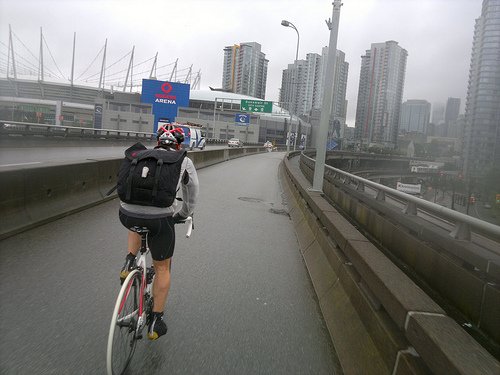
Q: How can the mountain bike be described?
A: A white and red mountain bike.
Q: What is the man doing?
A: Riding a bike.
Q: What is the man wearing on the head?
A: A helmet.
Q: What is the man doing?
A: Riding a bike.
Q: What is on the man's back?
A: A black backpack.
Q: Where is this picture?
A: In the middle of a downtown.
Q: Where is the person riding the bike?
A: On a path beside the road.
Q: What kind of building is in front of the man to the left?
A: An Arena.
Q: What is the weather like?
A: Foggy and cloudy.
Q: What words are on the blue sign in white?
A: Arena.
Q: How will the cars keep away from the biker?
A: With the concrete barrier between the road and bike path.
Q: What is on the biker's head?
A: A helmet.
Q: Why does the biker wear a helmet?
A: To prevent injury if he falls and hits his head.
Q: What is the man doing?
A: Riding bike.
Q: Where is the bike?
A: On the road.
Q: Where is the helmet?
A: On the man's head.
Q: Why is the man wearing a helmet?
A: Safety.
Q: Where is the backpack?
A: On the man.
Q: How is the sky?
A: Cloudy.